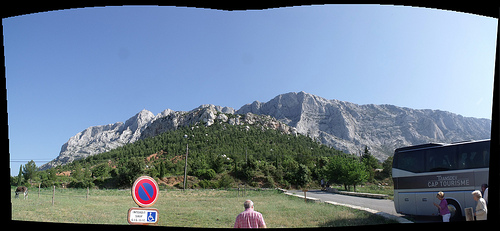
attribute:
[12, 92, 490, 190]
terrian — rocky, steep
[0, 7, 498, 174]
sky — blue, clear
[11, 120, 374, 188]
trees — lush, green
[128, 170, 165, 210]
circle — blue, red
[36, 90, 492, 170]
mountains — large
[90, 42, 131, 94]
sky — clear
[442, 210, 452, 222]
pants — white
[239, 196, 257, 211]
hair — gray